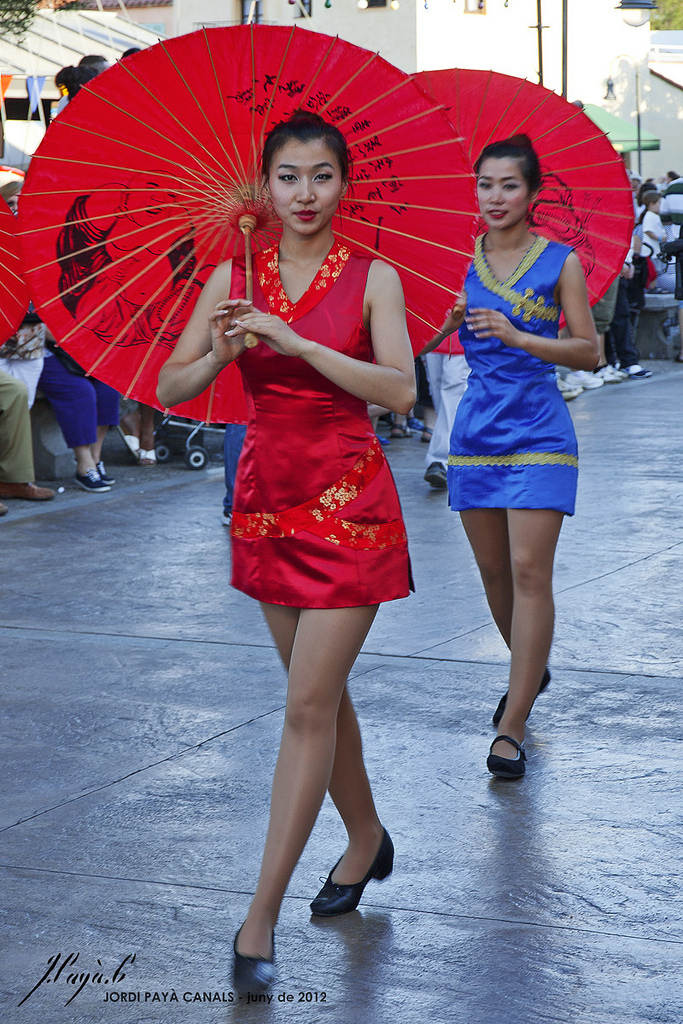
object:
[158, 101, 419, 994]
woman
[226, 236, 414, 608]
red dress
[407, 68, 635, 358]
parisol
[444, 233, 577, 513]
gold dress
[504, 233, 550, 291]
gold stripe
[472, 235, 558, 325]
gold stripe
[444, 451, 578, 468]
gold stripe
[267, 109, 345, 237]
face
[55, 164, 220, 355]
image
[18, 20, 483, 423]
umbrella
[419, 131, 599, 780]
woman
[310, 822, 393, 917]
shoe